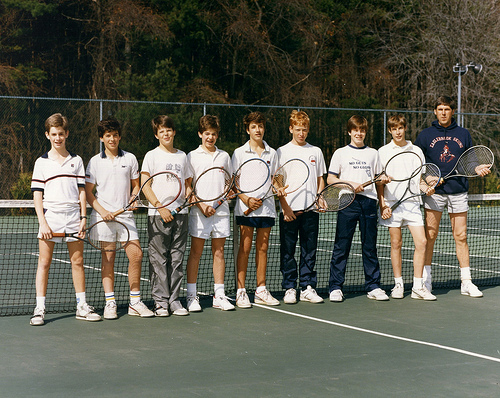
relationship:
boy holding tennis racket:
[141, 115, 197, 316] [171, 166, 232, 213]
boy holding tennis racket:
[231, 112, 290, 308] [242, 156, 310, 216]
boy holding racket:
[277, 107, 328, 304] [295, 181, 357, 216]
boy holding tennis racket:
[327, 112, 393, 302] [357, 149, 425, 189]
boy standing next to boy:
[29, 112, 103, 323] [82, 115, 156, 320]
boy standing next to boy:
[82, 115, 156, 320] [141, 115, 197, 316]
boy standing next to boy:
[141, 115, 197, 316] [187, 113, 237, 312]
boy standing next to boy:
[187, 113, 237, 312] [231, 111, 281, 308]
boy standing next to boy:
[231, 111, 281, 308] [277, 107, 328, 304]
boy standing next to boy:
[277, 107, 328, 304] [327, 112, 393, 302]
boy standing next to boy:
[327, 112, 393, 302] [375, 111, 440, 301]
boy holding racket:
[29, 112, 103, 323] [51, 220, 129, 252]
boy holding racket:
[82, 115, 156, 320] [113, 171, 181, 216]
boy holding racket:
[139, 111, 198, 317] [160, 166, 232, 223]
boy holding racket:
[187, 113, 237, 312] [204, 158, 270, 218]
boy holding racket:
[231, 111, 281, 308] [244, 158, 310, 216]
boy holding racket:
[327, 112, 393, 302] [361, 151, 423, 188]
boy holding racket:
[375, 111, 440, 301] [382, 163, 442, 220]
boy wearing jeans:
[277, 107, 328, 304] [278, 210, 318, 288]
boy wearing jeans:
[326, 115, 393, 301] [329, 194, 380, 291]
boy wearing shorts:
[29, 112, 103, 323] [35, 209, 84, 243]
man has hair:
[417, 92, 484, 298] [433, 94, 453, 112]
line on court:
[30, 249, 499, 362] [0, 212, 499, 397]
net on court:
[0, 193, 499, 317] [0, 212, 499, 397]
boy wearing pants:
[141, 115, 197, 316] [147, 212, 189, 306]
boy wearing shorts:
[231, 111, 281, 308] [236, 214, 276, 230]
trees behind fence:
[2, 3, 495, 196] [0, 93, 497, 216]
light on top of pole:
[473, 64, 483, 75] [454, 56, 464, 126]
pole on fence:
[96, 100, 105, 152] [0, 93, 497, 216]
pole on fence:
[200, 100, 206, 121] [0, 93, 497, 216]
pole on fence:
[383, 111, 386, 146] [0, 93, 497, 216]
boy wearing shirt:
[375, 111, 440, 301] [376, 136, 426, 201]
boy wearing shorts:
[231, 112, 290, 308] [240, 212, 276, 231]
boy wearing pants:
[141, 115, 197, 316] [147, 208, 185, 311]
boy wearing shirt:
[29, 112, 103, 323] [30, 148, 90, 215]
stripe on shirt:
[30, 171, 84, 185] [30, 148, 90, 215]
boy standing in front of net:
[375, 111, 440, 301] [0, 193, 498, 314]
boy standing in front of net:
[327, 112, 393, 302] [0, 193, 498, 314]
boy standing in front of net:
[231, 111, 281, 308] [0, 193, 498, 314]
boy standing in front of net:
[139, 111, 198, 317] [0, 193, 498, 314]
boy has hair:
[277, 107, 328, 304] [288, 107, 310, 127]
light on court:
[450, 59, 483, 75] [0, 212, 499, 397]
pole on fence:
[99, 100, 102, 153] [0, 94, 499, 190]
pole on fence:
[203, 105, 206, 116] [0, 94, 499, 190]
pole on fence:
[381, 109, 390, 147] [0, 94, 499, 190]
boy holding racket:
[30, 112, 102, 326] [41, 218, 131, 254]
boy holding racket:
[141, 115, 197, 316] [167, 162, 235, 217]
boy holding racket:
[231, 112, 290, 308] [167, 162, 235, 217]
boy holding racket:
[277, 109, 328, 303] [291, 180, 359, 215]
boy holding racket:
[377, 114, 437, 300] [291, 180, 359, 215]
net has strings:
[0, 193, 498, 314] [2, 206, 499, 315]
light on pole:
[473, 64, 483, 75] [453, 71, 462, 126]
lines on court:
[27, 239, 498, 363] [0, 212, 499, 397]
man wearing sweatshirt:
[415, 96, 492, 298] [414, 120, 482, 195]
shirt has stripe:
[30, 148, 90, 215] [30, 171, 84, 185]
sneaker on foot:
[30, 303, 48, 328] [27, 304, 47, 328]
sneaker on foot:
[75, 306, 99, 322] [72, 298, 102, 325]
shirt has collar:
[234, 141, 284, 218] [240, 138, 271, 157]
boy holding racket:
[187, 113, 237, 312] [212, 153, 270, 214]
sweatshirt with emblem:
[420, 124, 474, 194] [437, 140, 456, 163]